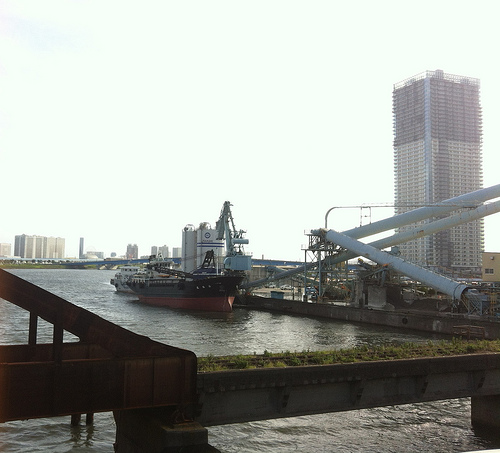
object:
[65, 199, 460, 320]
sea port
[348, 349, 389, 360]
land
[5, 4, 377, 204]
sky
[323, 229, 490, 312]
white pole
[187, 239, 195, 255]
walls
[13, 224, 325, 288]
background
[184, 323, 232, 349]
water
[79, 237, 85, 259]
building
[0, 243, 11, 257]
building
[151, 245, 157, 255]
building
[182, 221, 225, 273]
building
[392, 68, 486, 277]
building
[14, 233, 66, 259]
building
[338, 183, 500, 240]
white tubes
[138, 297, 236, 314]
bottom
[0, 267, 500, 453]
bridge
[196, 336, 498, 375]
grass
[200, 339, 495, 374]
plants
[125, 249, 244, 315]
boat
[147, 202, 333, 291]
concrete plant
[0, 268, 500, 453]
river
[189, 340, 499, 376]
passway